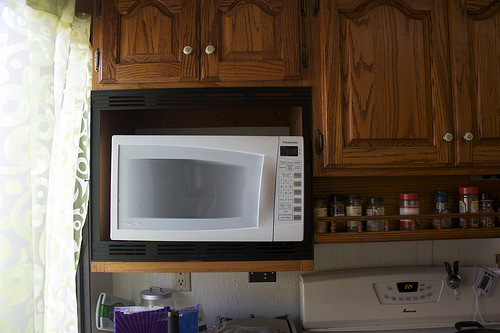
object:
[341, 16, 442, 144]
wooden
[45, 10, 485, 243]
cabinets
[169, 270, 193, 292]
electrical plug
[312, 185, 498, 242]
spice rack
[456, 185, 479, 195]
red cap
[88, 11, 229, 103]
door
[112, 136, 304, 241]
white microwave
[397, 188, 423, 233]
jar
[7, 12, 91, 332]
curtains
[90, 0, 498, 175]
cabinets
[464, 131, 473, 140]
knob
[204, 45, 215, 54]
knob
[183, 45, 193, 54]
knob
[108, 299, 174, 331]
purple bag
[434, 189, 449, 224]
bottle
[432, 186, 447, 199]
green cap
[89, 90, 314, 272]
stand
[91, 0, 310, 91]
cabinet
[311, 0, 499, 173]
cabinet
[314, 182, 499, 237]
stand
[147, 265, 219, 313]
electrical outlet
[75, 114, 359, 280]
microwave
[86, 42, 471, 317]
wall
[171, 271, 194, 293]
outlet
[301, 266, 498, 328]
oven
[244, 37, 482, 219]
cabin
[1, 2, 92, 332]
curtains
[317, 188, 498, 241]
assortment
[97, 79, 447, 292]
counter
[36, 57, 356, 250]
microwave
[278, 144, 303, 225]
display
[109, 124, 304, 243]
oven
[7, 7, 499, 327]
kitchen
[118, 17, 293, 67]
cabinets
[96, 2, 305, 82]
brown doors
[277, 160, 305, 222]
controls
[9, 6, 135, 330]
curtain.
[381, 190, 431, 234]
bottle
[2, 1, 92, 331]
curtain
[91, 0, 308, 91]
cabinets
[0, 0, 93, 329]
window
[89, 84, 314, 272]
cabinet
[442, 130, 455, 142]
knob